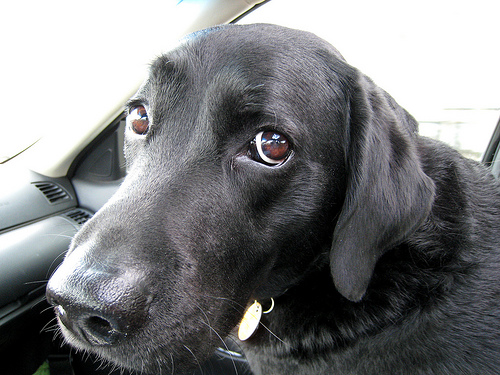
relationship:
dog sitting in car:
[46, 22, 499, 374] [2, 0, 499, 374]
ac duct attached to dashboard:
[32, 180, 72, 207] [0, 169, 78, 233]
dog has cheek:
[46, 22, 499, 374] [152, 280, 254, 373]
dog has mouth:
[46, 22, 499, 374] [51, 298, 239, 373]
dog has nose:
[46, 22, 499, 374] [45, 266, 152, 349]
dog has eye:
[46, 22, 499, 374] [248, 130, 294, 168]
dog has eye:
[46, 22, 499, 374] [123, 103, 152, 138]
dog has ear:
[46, 22, 499, 374] [328, 74, 437, 302]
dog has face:
[46, 22, 499, 374] [50, 98, 290, 368]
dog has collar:
[46, 22, 499, 374] [236, 258, 326, 343]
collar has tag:
[236, 258, 326, 343] [238, 301, 263, 342]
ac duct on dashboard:
[32, 180, 72, 207] [0, 169, 78, 233]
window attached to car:
[232, 0, 499, 169] [2, 0, 499, 374]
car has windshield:
[2, 0, 499, 374] [3, 0, 199, 165]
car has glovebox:
[2, 0, 499, 374] [1, 206, 104, 318]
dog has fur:
[46, 22, 499, 374] [46, 23, 499, 374]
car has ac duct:
[2, 0, 499, 374] [32, 180, 72, 207]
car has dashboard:
[2, 0, 499, 374] [0, 169, 78, 233]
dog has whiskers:
[46, 22, 499, 374] [26, 273, 285, 373]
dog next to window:
[46, 22, 499, 374] [232, 0, 499, 169]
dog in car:
[46, 22, 499, 374] [2, 0, 499, 374]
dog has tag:
[46, 22, 499, 374] [238, 301, 263, 342]